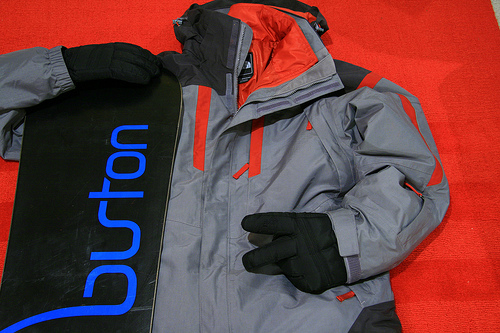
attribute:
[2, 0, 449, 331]
jacket — zipped up, red, gray, black, multi-colored, snow jacket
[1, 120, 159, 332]
logo — blue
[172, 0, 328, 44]
hood — black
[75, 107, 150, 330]
writing — large, blue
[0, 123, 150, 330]
word — blue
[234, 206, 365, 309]
glove — black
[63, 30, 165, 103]
glove — black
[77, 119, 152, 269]
snowboard — black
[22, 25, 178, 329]
snowboard — gray, black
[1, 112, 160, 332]
writing — blue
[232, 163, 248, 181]
pull — zipper pull, red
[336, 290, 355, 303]
pull — red, zipper pull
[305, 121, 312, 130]
pull — zipper pull, red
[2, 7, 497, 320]
carpet — red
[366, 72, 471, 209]
stripe — red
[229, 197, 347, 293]
glove — black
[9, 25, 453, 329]
jacket — flat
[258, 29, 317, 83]
lining — red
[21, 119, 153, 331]
writing — blue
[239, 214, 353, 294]
glove — black, snow glove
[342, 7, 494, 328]
backing — bright, red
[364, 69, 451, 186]
strip — red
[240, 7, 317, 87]
lining — red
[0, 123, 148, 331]
lettering — blue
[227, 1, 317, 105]
jacket lining — orange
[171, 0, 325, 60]
jacket's hood — Gray, Red